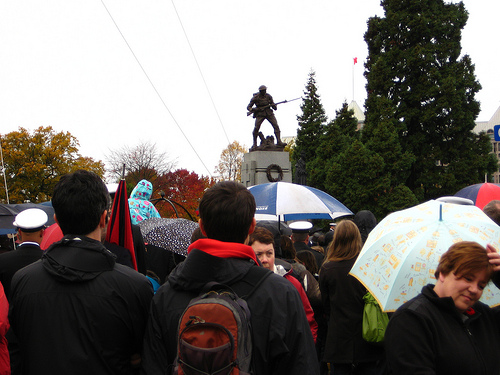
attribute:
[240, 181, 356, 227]
umbrella — blue, open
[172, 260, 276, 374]
backpack — orange, grey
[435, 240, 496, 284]
hair — short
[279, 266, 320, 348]
sweater — red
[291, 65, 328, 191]
tree — green, evergreen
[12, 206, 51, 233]
hat — white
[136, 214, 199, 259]
umbrella — purple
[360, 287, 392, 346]
bag — green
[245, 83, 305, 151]
statue — soldier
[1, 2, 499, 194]
sky — bright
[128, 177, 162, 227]
raincoat — blue, pink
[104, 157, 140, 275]
umbrella — closed, red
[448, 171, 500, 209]
umbrella — red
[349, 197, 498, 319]
umbrella — white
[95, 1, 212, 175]
wire — electrical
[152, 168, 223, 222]
tree — autumn colored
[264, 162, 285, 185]
circle — large, green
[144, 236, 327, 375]
jacket — black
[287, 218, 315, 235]
cap — white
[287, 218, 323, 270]
member — military